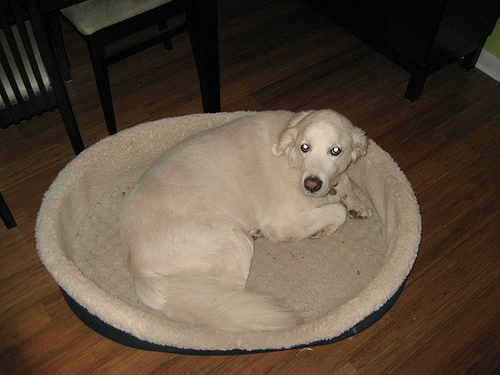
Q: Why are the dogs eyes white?
A: Reflection of flash.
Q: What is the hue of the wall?
A: Green.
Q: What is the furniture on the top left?
A: Chairs.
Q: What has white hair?
A: The dog.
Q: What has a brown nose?
A: The dog.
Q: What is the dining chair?
A: Wooden.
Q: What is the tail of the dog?
A: Fluffy.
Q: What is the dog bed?
A: Medium.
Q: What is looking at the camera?
A: The dog.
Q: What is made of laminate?
A: The floor.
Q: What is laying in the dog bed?
A: The white dog.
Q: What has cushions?
A: Two black chairs.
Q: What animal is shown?
A: A dog.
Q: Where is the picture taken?
A: A living room.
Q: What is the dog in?
A: The dog bed.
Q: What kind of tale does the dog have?
A: Fluffy.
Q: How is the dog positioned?
A: With paws curled up.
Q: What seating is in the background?
A: Chairs.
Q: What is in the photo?
A: A dog.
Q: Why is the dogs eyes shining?
A: Because of the camera light.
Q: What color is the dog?
A: White.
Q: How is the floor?
A: Wooden.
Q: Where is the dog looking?
A: At the photo.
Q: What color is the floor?
A: Brown.